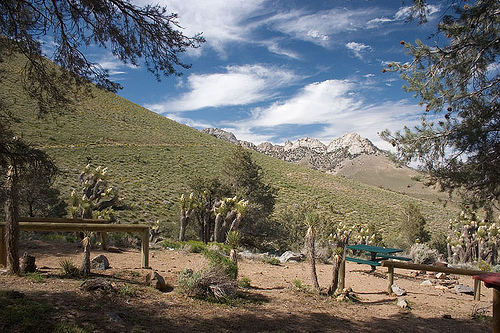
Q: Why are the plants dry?
A: It is the desert.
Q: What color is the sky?
A: Blue.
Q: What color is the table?
A: Green.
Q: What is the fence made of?
A: Wood.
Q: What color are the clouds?
A: White.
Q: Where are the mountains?
A: Passed the hill.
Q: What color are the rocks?
A: Grey.